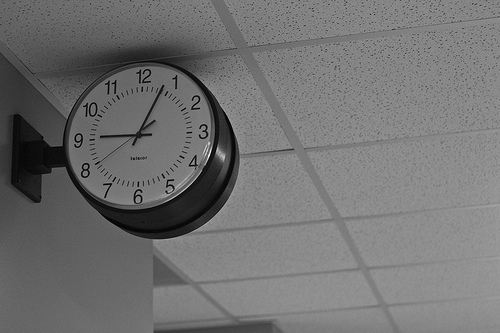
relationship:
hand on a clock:
[133, 83, 169, 149] [57, 56, 244, 236]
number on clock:
[197, 122, 208, 139] [52, 54, 247, 246]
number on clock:
[69, 71, 220, 241] [60, 56, 225, 218]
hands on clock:
[88, 79, 178, 156] [57, 56, 244, 236]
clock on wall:
[52, 54, 247, 246] [0, 167, 155, 329]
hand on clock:
[130, 82, 172, 150] [52, 54, 247, 246]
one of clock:
[169, 70, 183, 92] [60, 56, 225, 218]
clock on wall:
[52, 54, 247, 246] [6, 88, 57, 324]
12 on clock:
[131, 62, 158, 84] [68, 67, 247, 233]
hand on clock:
[78, 141, 128, 166] [52, 65, 222, 236]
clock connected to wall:
[52, 54, 247, 246] [16, 213, 78, 322]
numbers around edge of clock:
[82, 178, 190, 208] [57, 70, 211, 189]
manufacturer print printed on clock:
[124, 148, 149, 164] [52, 54, 247, 246]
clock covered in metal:
[52, 54, 247, 246] [109, 206, 195, 235]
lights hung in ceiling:
[150, 251, 184, 286] [1, 2, 496, 327]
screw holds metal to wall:
[13, 178, 21, 185] [10, 225, 115, 331]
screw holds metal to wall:
[33, 188, 43, 202] [10, 225, 115, 331]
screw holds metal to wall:
[38, 131, 47, 143] [10, 225, 115, 331]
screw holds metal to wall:
[13, 110, 23, 125] [10, 225, 115, 331]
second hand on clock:
[96, 137, 153, 166] [52, 54, 247, 246]